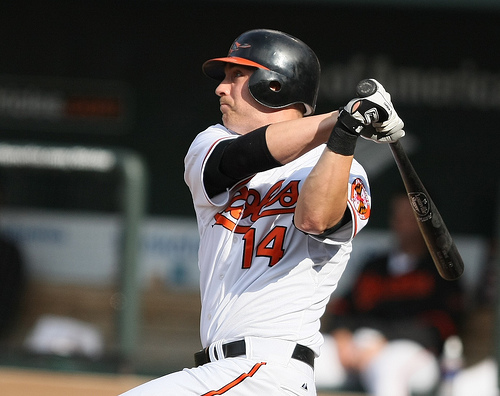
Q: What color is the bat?
A: Black.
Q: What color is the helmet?
A: Black.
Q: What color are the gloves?
A: Black.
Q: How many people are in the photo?
A: One.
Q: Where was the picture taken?
A: On a baseball field.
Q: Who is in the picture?
A: A man.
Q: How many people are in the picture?
A: 1.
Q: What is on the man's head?
A: Helmet.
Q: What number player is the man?
A: 14.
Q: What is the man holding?
A: A bat.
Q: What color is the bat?
A: Black.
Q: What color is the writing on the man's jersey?
A: Orange.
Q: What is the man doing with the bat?
A: Swinging.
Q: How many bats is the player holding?
A: 1.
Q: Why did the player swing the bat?
A: Hit ball.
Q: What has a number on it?
A: Shirt.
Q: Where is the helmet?
A: Player's head.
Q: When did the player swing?
A: After ball was pitched.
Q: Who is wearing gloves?
A: Batter.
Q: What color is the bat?
A: Black.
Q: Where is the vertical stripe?
A: Pants.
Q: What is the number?
A: 14.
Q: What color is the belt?
A: Black.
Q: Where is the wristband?
A: On the player's left wrist.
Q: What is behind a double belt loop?
A: A black belt.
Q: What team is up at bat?
A: The Orioles.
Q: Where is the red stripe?
A: On the player's pant leg.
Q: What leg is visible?
A: The left leg.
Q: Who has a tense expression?
A: The batter.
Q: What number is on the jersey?
A: 14.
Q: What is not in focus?
A: A watching player, in the dugout.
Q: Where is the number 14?
A: On the man's shirt.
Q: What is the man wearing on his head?
A: A helmet.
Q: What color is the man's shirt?
A: Orange and white.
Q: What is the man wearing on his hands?
A: Gloves.